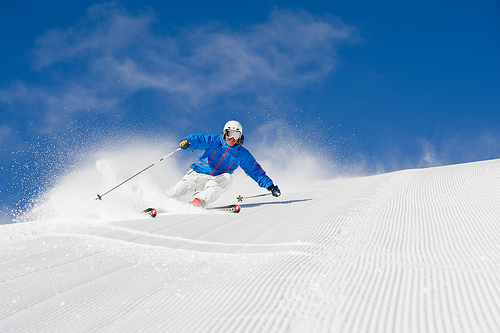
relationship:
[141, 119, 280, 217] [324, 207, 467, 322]
blue coat in snow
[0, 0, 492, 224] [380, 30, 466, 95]
cloud in sky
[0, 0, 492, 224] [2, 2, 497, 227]
cloud in sky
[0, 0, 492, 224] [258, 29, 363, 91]
cloud in sky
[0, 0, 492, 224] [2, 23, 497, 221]
cloud in blue sky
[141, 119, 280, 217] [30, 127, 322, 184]
blue coat on on hill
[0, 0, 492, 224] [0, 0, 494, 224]
cloud in blue sky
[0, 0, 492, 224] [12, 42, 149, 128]
cloud in sky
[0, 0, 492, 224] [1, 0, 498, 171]
cloud in sky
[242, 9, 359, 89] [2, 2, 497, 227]
cloud in sky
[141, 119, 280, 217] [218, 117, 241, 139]
blue coat wearing helmet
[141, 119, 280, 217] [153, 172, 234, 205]
blue coat wearing pants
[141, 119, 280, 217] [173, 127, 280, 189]
blue coat wearing blue coat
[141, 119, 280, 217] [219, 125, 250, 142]
blue coat wearing goggles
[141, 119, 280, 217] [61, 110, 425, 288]
blue coat coming down hill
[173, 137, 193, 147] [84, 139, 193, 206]
hand on ski pole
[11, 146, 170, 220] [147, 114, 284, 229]
snow behind skier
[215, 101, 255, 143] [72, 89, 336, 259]
helmet of a skier